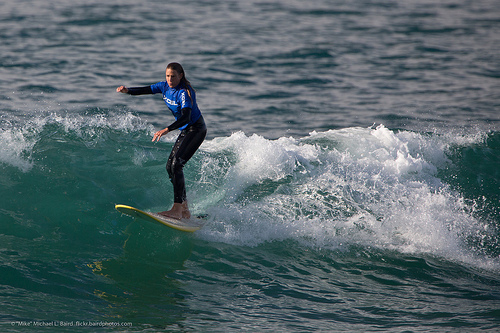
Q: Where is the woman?
A: On the board.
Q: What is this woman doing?
A: Surfing.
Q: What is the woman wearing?
A: Wetsuit.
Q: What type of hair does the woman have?
A: Long hair.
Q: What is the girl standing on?
A: A surfboard.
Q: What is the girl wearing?
A: A wet suit.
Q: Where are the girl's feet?
A: On the surfboard.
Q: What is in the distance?
A: Water.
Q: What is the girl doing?
A: Surfing.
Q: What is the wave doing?
A: Falling.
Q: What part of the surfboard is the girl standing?
A: The middle.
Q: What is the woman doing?
A: Surfing.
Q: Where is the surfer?
A: In the ocean.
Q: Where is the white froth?
A: Behind the surfer.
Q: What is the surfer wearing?
A: Blue and black wetsuit.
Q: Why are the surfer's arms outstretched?
A: For balance.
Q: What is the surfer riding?
A: A wave.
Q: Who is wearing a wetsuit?
A: The surfer.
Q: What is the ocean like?
A: Greenish blue.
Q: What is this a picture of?
A: A woman surfing.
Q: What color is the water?
A: Blue-green.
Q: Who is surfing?
A: A woman.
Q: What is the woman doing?
A: Surfing.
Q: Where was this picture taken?
A: At a beach.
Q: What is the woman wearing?
A: A wetsuit.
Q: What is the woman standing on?
A: A surfboard.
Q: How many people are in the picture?
A: One.